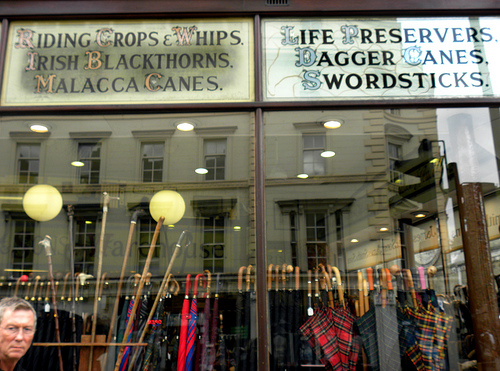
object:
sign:
[0, 238, 223, 261]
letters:
[14, 28, 91, 50]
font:
[8, 22, 248, 102]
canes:
[88, 192, 119, 371]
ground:
[251, 147, 293, 176]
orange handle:
[384, 268, 394, 290]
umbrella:
[376, 266, 403, 370]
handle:
[417, 266, 427, 289]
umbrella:
[185, 273, 206, 371]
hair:
[0, 293, 36, 324]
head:
[1, 296, 37, 369]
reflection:
[260, 102, 498, 369]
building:
[0, 0, 499, 368]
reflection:
[0, 109, 258, 368]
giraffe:
[103, 111, 386, 281]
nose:
[15, 328, 24, 342]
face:
[0, 310, 35, 361]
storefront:
[2, 0, 497, 368]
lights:
[194, 167, 209, 175]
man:
[0, 296, 37, 371]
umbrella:
[300, 264, 363, 371]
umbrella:
[425, 264, 452, 370]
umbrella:
[400, 266, 449, 371]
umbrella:
[356, 264, 376, 370]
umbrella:
[293, 265, 303, 371]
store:
[6, 1, 493, 368]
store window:
[4, 104, 500, 370]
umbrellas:
[149, 273, 178, 370]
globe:
[149, 190, 186, 226]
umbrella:
[175, 273, 193, 370]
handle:
[192, 273, 206, 298]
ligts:
[320, 150, 337, 158]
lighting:
[176, 122, 195, 131]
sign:
[0, 15, 500, 108]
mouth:
[8, 344, 25, 351]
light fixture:
[71, 161, 85, 167]